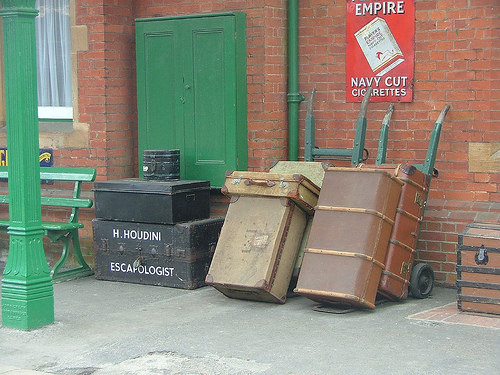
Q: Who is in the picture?
A: No one.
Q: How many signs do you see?
A: One.